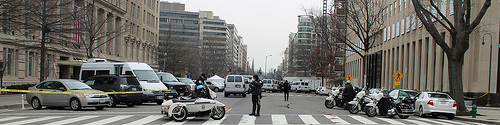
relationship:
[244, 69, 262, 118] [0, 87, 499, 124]
officer standing in a street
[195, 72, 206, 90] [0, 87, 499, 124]
officer standing in a street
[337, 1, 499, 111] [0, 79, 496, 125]
building along road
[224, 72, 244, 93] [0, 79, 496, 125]
van driving down road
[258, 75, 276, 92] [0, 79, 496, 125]
van driving down road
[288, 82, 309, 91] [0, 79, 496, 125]
van driving down road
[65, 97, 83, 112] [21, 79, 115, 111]
wheel on car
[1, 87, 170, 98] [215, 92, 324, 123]
tape blocks street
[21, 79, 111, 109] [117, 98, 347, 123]
car on street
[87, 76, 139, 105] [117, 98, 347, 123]
car on street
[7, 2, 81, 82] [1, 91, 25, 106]
tree near sidewalk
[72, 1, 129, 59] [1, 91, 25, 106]
tree near sidewalk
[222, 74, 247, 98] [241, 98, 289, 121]
van on a street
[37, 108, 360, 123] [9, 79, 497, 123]
white lines painted on road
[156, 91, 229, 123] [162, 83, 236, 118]
car with sidecar